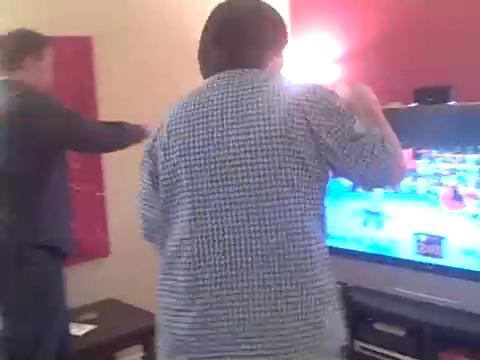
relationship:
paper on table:
[74, 315, 113, 345] [77, 294, 148, 327]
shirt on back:
[183, 109, 291, 210] [158, 109, 315, 312]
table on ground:
[77, 294, 148, 327] [122, 338, 146, 359]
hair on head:
[194, 8, 281, 61] [188, 18, 338, 120]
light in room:
[278, 23, 362, 107] [77, 8, 445, 358]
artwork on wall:
[49, 20, 147, 300] [370, 18, 471, 70]